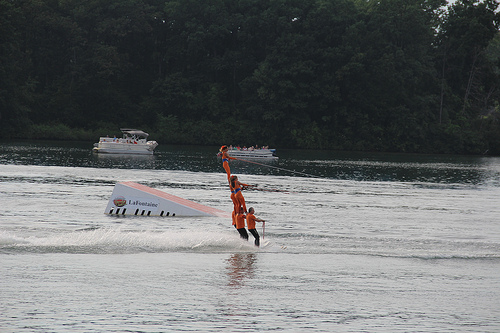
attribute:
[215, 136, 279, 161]
boat — smaller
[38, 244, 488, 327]
waters — calm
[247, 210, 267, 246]
person — surfing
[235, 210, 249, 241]
person — surfing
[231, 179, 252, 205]
person — surfing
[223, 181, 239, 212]
person — surfing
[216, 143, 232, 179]
person — surfing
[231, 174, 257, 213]
person — surfing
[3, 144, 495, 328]
water — sparkling, white